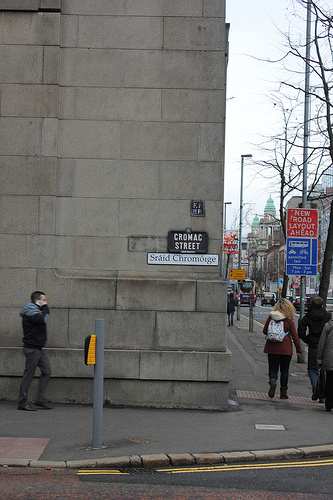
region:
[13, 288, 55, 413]
A man is on a sidewalk.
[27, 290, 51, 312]
A man is talking on a cellphone.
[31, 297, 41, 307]
The color of a cellphone is white.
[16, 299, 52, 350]
A man is wearing a blue and black jacket.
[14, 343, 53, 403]
A man is wearing gray pants.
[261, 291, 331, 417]
Three people are walking next to each other.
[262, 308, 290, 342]
A woman is carring a backpack.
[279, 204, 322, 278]
Two signs are visible.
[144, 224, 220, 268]
Two signs are on a building.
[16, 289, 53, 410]
guy in black talking on the phone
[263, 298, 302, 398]
woman with a white backpack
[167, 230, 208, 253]
black sign on the side of the building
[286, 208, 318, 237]
red sign on a metal pole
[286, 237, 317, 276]
blue sign under a red sign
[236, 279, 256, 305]
white bus in the middle of the street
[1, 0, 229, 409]
big building made of concrete blocks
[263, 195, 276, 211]
blue top of a big building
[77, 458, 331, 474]
yellow lines on the side of the street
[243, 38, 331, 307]
tall tree on the side of the street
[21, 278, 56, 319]
head of a person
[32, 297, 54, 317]
arm of a person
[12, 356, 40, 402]
leg of a person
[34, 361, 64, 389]
leg of a person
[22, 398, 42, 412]
feet of a person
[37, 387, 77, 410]
feet of a person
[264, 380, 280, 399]
feet of a person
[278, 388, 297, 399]
feet of a person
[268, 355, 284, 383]
leg of a person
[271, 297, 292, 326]
head of a person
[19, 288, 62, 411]
A man walking on the sidewalk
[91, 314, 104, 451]
A pole in the sidewalk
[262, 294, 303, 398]
A woman walking on the sidewalk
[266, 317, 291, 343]
A small backpack on the woman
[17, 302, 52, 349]
A black and gray hoodie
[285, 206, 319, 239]
A red sign with white letters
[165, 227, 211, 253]
A street sign on the building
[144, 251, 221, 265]
A white sign with black letters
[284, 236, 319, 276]
A blue sign on a pole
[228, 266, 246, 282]
A yellow sign on a pole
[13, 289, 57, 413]
man in a black and gray jacket talking on his phone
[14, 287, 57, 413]
man walking with a phone in his hand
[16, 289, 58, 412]
man walking with a phone pressed against his ear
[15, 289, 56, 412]
man wearing black and gray clothing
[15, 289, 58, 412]
man on his phone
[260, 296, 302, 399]
blonde haired woman wearing a brown coat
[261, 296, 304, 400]
curly haired woman wearing a backpack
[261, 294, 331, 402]
man and woman walking together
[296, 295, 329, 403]
man in a black coat walking on a street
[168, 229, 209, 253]
black and white cromac street sign